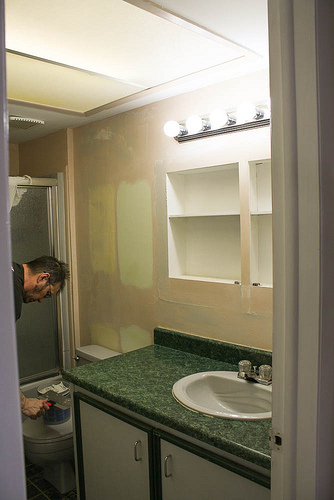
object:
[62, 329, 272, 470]
counter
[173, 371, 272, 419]
sink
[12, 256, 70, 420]
man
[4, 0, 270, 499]
bathroom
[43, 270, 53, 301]
glasses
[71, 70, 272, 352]
wall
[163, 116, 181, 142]
lights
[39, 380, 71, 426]
paint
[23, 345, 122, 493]
toilet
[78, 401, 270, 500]
cupboard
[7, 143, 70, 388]
shower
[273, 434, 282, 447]
hole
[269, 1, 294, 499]
door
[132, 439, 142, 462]
handle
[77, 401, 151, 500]
door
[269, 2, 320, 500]
door frame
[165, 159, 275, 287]
cabinet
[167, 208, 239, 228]
shelves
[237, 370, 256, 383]
faucet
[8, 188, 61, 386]
glass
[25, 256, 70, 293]
hair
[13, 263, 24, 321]
shirt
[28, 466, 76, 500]
tile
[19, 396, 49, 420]
hand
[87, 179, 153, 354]
paint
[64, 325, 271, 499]
vanity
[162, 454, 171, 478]
handles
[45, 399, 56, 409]
tool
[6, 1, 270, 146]
ceiling